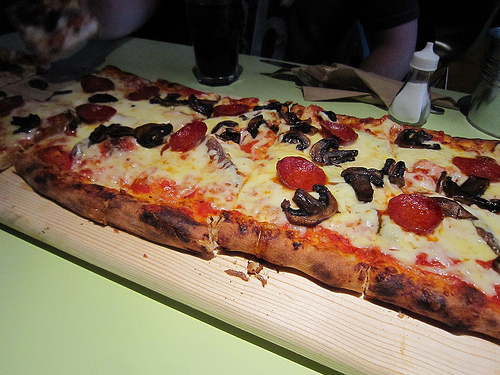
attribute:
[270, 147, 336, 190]
piece — curled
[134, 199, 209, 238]
area — charred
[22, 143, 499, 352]
crust — pizza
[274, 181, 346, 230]
slice — mushroom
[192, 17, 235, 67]
beverage — dark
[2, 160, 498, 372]
piece — blonde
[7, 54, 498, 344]
pizza — large, oblong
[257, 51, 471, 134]
napkins — brown, paper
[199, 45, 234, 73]
liquid — brown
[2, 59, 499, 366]
board — brown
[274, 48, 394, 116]
napkin — Brown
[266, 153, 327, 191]
pepperoni — Red 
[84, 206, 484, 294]
crust — brown , Golden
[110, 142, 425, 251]
cheese — White, melted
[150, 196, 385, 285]
sauce — Red 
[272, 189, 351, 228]
mushroom — Piece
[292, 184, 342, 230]
mushroom — Piece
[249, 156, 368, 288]
pizza — slice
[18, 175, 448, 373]
board — cutting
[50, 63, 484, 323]
pizza — mushrooms , slice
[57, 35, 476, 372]
table — wooden , brown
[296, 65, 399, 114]
napkin — brown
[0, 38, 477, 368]
table — green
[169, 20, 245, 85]
cup — soda, black 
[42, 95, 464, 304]
pizza — sliced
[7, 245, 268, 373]
tablecloth — green